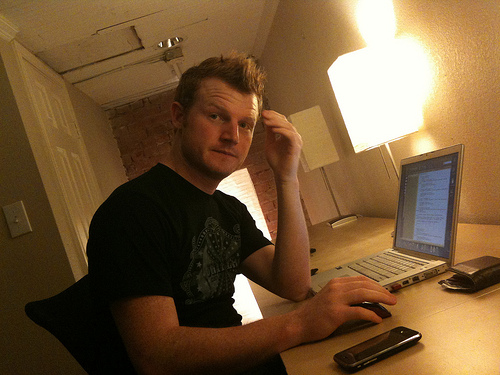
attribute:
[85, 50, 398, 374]
man — looking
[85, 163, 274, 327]
shirt — black, short sleeved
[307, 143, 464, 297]
laptop — open, on, small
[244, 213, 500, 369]
desk — long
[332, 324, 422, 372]
phone — black, rectangle, large, silver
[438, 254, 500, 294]
wallet — thick, leather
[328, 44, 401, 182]
lamp — on, white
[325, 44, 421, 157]
shade — square, on, white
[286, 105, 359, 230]
lamp — off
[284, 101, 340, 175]
shade — square, box, off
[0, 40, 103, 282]
door — white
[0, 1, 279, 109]
ceiling — damaged, broken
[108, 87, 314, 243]
wall — brick, red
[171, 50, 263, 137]
hair — red, receding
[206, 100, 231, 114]
brow — wrinkeld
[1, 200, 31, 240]
light switch — down, white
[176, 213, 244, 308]
design — green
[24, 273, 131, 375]
chair — black